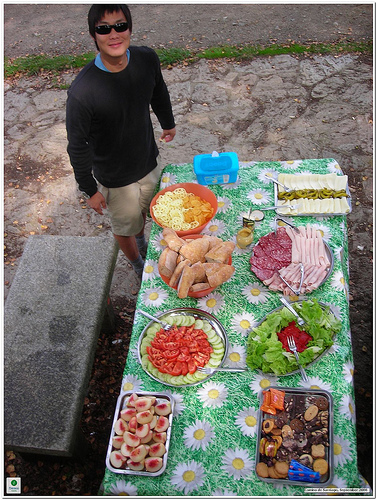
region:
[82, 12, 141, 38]
man wearing glasses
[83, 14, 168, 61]
a man with a smile on his face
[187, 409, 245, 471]
flowers on the table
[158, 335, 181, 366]
tomatoes on a plate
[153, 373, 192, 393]
cucumbers on a plate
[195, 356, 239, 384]
a fork on the plate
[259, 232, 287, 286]
meat on a tray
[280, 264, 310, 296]
tong on the table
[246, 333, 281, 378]
lettuce on a plate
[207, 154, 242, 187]
wipes on the table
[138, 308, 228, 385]
Vegetables on the plate.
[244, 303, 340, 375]
The lettuce is green.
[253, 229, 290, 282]
There is salami on this plate.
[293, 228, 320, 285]
There is turkey on this plate.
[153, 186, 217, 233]
Looks like there are two different types of chips here.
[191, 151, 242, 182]
The towel case is blue.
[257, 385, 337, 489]
Nice assortment of cookies on this tray.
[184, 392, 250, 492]
There are flowers on this tablecloth.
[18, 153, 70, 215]
The street is dirty.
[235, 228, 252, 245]
The mustard is yellow.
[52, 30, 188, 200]
THE MAN IS WEARING A BLACK, LONG SLEEVED SHIRT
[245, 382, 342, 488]
THIS IS A PAN OF ASSORTED COOKIES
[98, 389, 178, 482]
THIS IS A TRAY OF SLICED PEACHES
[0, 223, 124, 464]
THIS IS A STONE PICNIC BENCH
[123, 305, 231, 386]
THIS IS A BOWL OF SLICED TOMATOES AND CUCUMBERS TO ADD TO YOUR SALAD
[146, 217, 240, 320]
THIS IS A BOWL FULL OF BREAD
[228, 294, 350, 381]
THIS IS A BOWL OF SALAD WITH TWO FORKS ON TOP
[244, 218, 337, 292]
THIS IS A TRAY OF DELI MEATS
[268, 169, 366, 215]
THIS IS A TRAY OF CHEESES AND PICKLES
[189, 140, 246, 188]
THIS IS A BOX OF WET WIPES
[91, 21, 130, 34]
dark black sunglasses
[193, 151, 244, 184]
a blue tub of baby wipes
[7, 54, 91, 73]
a section of green grass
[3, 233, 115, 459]
a concrete bench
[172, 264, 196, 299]
a piece of bread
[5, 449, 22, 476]
brown leaves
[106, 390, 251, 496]
part of a sunflower tablecloth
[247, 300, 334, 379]
a tray of salad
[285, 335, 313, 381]
a long silver fork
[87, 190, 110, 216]
the hand of a man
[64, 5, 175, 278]
standing man looking up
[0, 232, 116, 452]
top of stone bench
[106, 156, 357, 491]
flowered cloth on table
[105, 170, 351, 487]
trays and bowls of food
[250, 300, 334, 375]
oval tray with lettuce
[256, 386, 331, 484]
sqaure tray of cookies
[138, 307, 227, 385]
slices of food in metal tray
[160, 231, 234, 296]
loafs of bread in bowl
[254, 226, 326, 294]
two kinds of meat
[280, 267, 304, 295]
pair of metal tongs